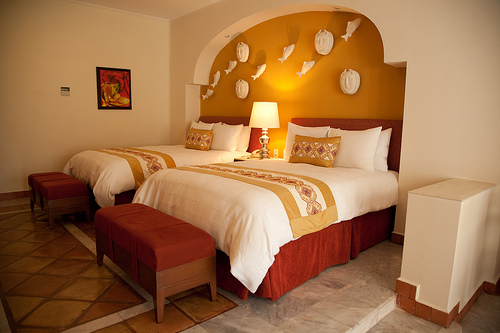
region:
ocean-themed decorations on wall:
[178, 17, 369, 106]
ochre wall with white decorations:
[197, 10, 409, 118]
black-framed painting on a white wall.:
[88, 58, 143, 115]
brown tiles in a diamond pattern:
[1, 192, 241, 329]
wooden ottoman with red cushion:
[93, 199, 220, 326]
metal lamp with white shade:
[246, 96, 283, 159]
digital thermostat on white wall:
[58, 77, 80, 106]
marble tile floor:
[241, 241, 399, 331]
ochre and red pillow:
[283, 121, 385, 173]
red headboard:
[286, 117, 403, 243]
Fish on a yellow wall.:
[214, 30, 316, 83]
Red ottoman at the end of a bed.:
[45, 185, 260, 315]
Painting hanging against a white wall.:
[44, 35, 154, 144]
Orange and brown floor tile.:
[6, 174, 261, 331]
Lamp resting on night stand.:
[198, 64, 315, 185]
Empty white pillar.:
[376, 152, 497, 329]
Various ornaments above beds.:
[173, 21, 445, 117]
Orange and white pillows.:
[271, 123, 383, 248]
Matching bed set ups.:
[72, 67, 388, 280]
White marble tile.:
[296, 280, 461, 331]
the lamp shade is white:
[238, 95, 281, 173]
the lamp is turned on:
[245, 93, 297, 163]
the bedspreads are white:
[70, 129, 392, 255]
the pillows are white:
[277, 117, 397, 172]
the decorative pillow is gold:
[293, 133, 344, 175]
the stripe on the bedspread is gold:
[190, 155, 346, 235]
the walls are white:
[5, 11, 180, 180]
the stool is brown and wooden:
[72, 194, 224, 314]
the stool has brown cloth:
[86, 197, 220, 270]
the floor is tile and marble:
[8, 248, 404, 331]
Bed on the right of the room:
[148, 131, 390, 303]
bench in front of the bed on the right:
[89, 191, 211, 331]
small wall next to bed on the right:
[390, 169, 475, 326]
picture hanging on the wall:
[93, 56, 150, 113]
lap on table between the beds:
[244, 93, 294, 165]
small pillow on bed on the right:
[288, 130, 343, 166]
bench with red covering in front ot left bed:
[24, 167, 91, 229]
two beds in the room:
[30, 98, 398, 320]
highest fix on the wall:
[329, 12, 368, 46]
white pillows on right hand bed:
[286, 118, 398, 178]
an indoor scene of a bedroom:
[0, 1, 499, 332]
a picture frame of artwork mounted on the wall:
[94, 66, 132, 108]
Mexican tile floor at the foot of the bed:
[0, 223, 90, 331]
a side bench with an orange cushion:
[95, 200, 217, 321]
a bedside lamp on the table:
[248, 100, 279, 160]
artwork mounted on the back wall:
[277, 42, 294, 63]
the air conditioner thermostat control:
[60, 84, 70, 97]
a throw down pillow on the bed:
[287, 133, 340, 170]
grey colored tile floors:
[235, 242, 445, 330]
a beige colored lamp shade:
[248, 102, 279, 128]